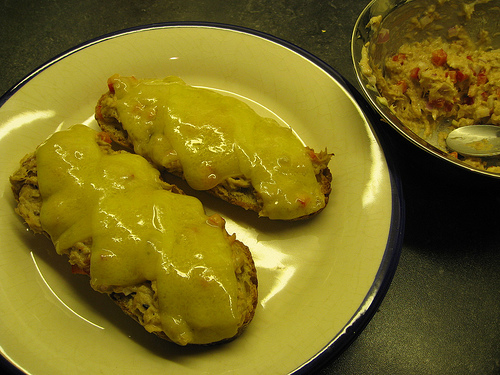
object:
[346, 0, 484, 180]
edge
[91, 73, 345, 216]
sandwich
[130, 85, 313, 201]
cheese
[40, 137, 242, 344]
cheese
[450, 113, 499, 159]
spoon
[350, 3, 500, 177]
bowl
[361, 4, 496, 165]
filling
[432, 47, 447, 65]
tomato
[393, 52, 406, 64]
tomato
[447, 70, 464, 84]
tomato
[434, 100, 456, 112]
tomato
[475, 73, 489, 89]
tomato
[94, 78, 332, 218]
bread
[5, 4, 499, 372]
surface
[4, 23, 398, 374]
plate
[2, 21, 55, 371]
edge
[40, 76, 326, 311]
sauce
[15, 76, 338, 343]
chicken